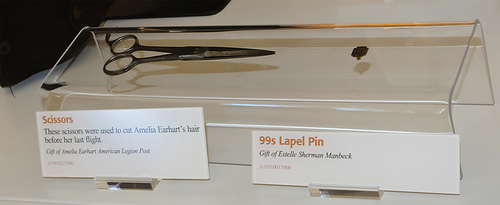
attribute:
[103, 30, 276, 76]
scissors — steel, displayed, metal, grey, old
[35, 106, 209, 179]
card — white, paper, informational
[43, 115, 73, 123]
text — orange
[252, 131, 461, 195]
card — white, paper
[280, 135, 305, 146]
text — orange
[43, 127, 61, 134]
text — black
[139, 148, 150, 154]
text — italicized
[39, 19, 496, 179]
display — clear, lucite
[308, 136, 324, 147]
text — orange